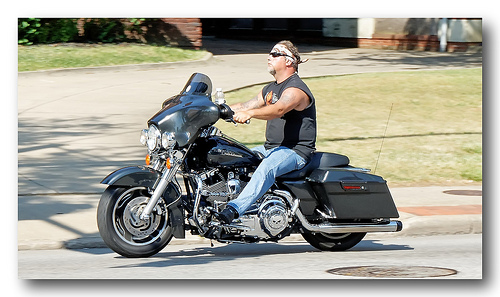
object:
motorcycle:
[96, 72, 403, 258]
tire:
[97, 174, 178, 259]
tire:
[299, 225, 368, 252]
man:
[220, 40, 317, 223]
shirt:
[261, 73, 317, 161]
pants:
[225, 146, 307, 219]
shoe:
[219, 206, 236, 224]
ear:
[285, 57, 294, 66]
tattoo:
[280, 93, 297, 104]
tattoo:
[232, 95, 264, 110]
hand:
[233, 112, 252, 124]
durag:
[270, 44, 309, 63]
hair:
[279, 40, 302, 74]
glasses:
[268, 52, 296, 61]